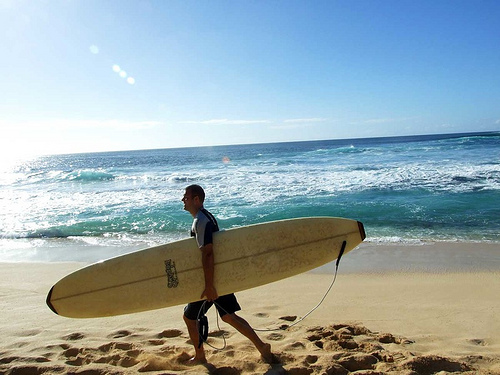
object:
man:
[180, 184, 273, 366]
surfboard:
[45, 216, 365, 319]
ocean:
[0, 132, 499, 244]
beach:
[0, 240, 499, 374]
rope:
[195, 240, 347, 350]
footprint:
[156, 329, 183, 339]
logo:
[163, 259, 179, 289]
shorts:
[183, 293, 242, 321]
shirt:
[189, 207, 220, 248]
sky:
[0, 0, 498, 157]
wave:
[5, 166, 121, 188]